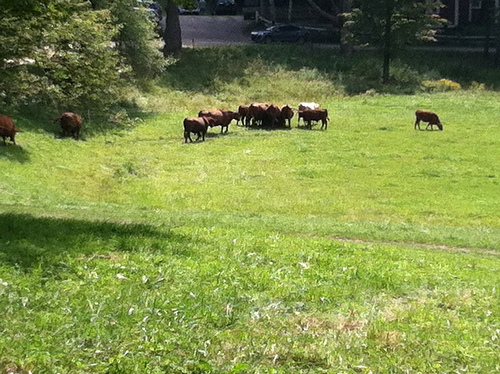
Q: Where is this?
A: This is at the field.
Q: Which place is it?
A: It is a field.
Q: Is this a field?
A: Yes, it is a field.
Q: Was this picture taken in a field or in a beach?
A: It was taken at a field.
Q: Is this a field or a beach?
A: It is a field.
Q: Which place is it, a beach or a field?
A: It is a field.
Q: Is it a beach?
A: No, it is a field.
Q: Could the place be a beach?
A: No, it is a field.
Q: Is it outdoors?
A: Yes, it is outdoors.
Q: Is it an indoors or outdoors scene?
A: It is outdoors.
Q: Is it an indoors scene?
A: No, it is outdoors.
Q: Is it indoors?
A: No, it is outdoors.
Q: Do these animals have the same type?
A: Yes, all the animals are cows.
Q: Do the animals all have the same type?
A: Yes, all the animals are cows.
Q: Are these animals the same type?
A: Yes, all the animals are cows.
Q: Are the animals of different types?
A: No, all the animals are cows.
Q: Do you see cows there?
A: Yes, there is a cow.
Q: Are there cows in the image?
A: Yes, there is a cow.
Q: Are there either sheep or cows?
A: Yes, there is a cow.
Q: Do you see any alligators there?
A: No, there are no alligators.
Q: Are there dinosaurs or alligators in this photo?
A: No, there are no alligators or dinosaurs.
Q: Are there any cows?
A: Yes, there are cows.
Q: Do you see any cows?
A: Yes, there are cows.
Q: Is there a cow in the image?
A: Yes, there are cows.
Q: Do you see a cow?
A: Yes, there are cows.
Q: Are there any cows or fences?
A: Yes, there are cows.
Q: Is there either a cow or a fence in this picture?
A: Yes, there are cows.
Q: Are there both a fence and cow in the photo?
A: No, there are cows but no fences.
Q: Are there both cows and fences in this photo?
A: No, there are cows but no fences.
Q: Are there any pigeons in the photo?
A: No, there are no pigeons.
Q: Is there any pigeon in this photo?
A: No, there are no pigeons.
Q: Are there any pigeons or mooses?
A: No, there are no pigeons or mooses.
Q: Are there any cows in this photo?
A: Yes, there is a cow.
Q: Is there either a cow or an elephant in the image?
A: Yes, there is a cow.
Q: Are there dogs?
A: No, there are no dogs.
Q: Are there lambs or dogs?
A: No, there are no dogs or lambs.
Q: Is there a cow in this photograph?
A: Yes, there is a cow.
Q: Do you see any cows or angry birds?
A: Yes, there is a cow.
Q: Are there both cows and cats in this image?
A: No, there is a cow but no cats.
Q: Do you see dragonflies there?
A: No, there are no dragonflies.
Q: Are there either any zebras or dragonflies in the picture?
A: No, there are no dragonflies or zebras.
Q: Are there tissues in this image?
A: No, there are no tissues.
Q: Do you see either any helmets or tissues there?
A: No, there are no tissues or helmets.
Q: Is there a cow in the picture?
A: Yes, there is a cow.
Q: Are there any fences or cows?
A: Yes, there is a cow.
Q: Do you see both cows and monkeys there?
A: No, there is a cow but no monkeys.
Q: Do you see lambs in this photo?
A: No, there are no lambs.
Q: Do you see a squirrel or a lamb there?
A: No, there are no lambs or squirrels.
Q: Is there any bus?
A: No, there are no buses.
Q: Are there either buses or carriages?
A: No, there are no buses or carriages.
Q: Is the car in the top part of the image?
A: Yes, the car is in the top of the image.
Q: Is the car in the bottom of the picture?
A: No, the car is in the top of the image.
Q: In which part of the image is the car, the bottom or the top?
A: The car is in the top of the image.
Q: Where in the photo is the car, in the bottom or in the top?
A: The car is in the top of the image.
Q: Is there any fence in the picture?
A: No, there are no fences.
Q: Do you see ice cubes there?
A: No, there are no ice cubes.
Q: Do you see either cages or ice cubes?
A: No, there are no ice cubes or cages.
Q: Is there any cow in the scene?
A: Yes, there is a cow.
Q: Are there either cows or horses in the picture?
A: Yes, there is a cow.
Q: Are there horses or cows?
A: Yes, there is a cow.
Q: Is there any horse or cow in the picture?
A: Yes, there is a cow.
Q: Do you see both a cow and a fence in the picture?
A: No, there is a cow but no fences.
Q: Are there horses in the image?
A: No, there are no horses.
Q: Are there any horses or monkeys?
A: No, there are no horses or monkeys.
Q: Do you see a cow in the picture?
A: Yes, there is a cow.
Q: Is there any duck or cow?
A: Yes, there is a cow.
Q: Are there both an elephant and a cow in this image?
A: No, there is a cow but no elephants.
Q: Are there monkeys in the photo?
A: No, there are no monkeys.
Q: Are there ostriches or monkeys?
A: No, there are no monkeys or ostriches.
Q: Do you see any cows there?
A: Yes, there is a cow.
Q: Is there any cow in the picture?
A: Yes, there is a cow.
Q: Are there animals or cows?
A: Yes, there is a cow.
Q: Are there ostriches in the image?
A: No, there are no ostriches.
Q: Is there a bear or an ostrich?
A: No, there are no ostriches or bears.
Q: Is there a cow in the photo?
A: Yes, there is a cow.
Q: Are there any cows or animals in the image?
A: Yes, there is a cow.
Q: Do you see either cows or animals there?
A: Yes, there is a cow.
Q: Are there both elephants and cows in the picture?
A: No, there is a cow but no elephants.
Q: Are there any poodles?
A: No, there are no poodles.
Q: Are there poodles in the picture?
A: No, there are no poodles.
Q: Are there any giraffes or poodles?
A: No, there are no poodles or giraffes.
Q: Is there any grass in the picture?
A: Yes, there is grass.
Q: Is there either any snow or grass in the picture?
A: Yes, there is grass.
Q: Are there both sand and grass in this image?
A: No, there is grass but no sand.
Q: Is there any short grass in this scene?
A: Yes, there is short grass.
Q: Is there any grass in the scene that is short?
A: Yes, there is grass that is short.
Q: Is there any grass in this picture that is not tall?
A: Yes, there is short grass.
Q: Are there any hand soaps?
A: No, there are no hand soaps.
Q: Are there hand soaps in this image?
A: No, there are no hand soaps.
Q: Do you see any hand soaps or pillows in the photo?
A: No, there are no hand soaps or pillows.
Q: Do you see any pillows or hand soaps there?
A: No, there are no hand soaps or pillows.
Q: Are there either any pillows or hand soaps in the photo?
A: No, there are no hand soaps or pillows.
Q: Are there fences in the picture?
A: No, there are no fences.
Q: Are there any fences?
A: No, there are no fences.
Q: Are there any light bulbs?
A: No, there are no light bulbs.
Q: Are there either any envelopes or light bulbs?
A: No, there are no light bulbs or envelopes.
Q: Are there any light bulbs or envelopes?
A: No, there are no light bulbs or envelopes.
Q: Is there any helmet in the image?
A: No, there are no helmets.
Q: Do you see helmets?
A: No, there are no helmets.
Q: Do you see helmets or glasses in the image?
A: No, there are no helmets or glasses.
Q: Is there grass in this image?
A: Yes, there is grass.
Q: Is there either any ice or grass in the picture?
A: Yes, there is grass.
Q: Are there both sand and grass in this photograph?
A: No, there is grass but no sand.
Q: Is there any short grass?
A: Yes, there is short grass.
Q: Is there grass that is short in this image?
A: Yes, there is short grass.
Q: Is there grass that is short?
A: Yes, there is grass that is short.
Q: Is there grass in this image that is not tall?
A: Yes, there is short grass.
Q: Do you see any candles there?
A: No, there are no candles.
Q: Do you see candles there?
A: No, there are no candles.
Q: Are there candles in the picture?
A: No, there are no candles.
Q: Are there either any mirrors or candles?
A: No, there are no candles or mirrors.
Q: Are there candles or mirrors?
A: No, there are no candles or mirrors.